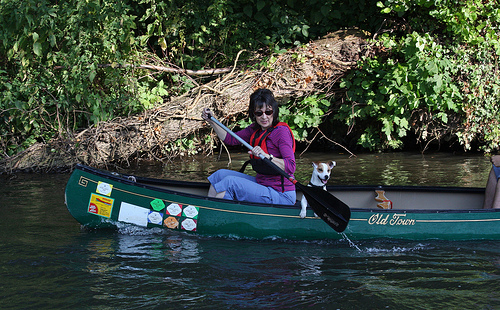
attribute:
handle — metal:
[200, 105, 266, 161]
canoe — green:
[37, 156, 493, 264]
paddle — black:
[202, 107, 351, 234]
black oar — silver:
[290, 179, 349, 236]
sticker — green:
[147, 191, 164, 212]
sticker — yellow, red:
[85, 192, 112, 217]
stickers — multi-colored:
[84, 181, 206, 241]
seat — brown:
[369, 182, 394, 212]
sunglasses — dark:
[252, 109, 277, 115]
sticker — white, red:
[162, 200, 184, 217]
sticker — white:
[181, 204, 200, 220]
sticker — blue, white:
[147, 208, 165, 228]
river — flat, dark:
[0, 150, 497, 308]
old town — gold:
[365, 211, 415, 229]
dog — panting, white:
[299, 157, 336, 220]